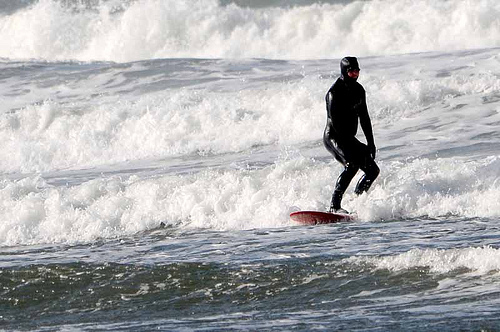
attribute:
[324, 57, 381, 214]
person — surfing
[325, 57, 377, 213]
wet suit — shiny, black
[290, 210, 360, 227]
surfboard — red